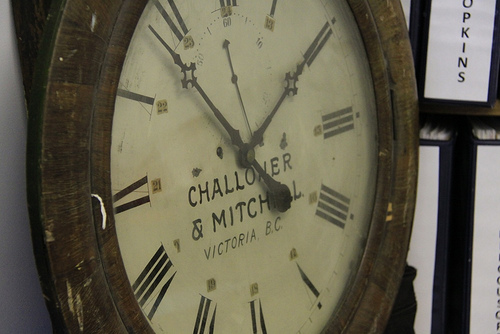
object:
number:
[130, 242, 179, 324]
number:
[315, 105, 363, 140]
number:
[299, 18, 339, 71]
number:
[190, 293, 220, 333]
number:
[293, 258, 323, 297]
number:
[110, 174, 155, 214]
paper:
[420, 0, 495, 103]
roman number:
[245, 297, 270, 333]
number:
[113, 86, 159, 119]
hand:
[248, 36, 318, 149]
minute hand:
[142, 21, 293, 214]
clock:
[10, 0, 422, 333]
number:
[312, 183, 353, 229]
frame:
[5, 0, 422, 333]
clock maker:
[185, 150, 307, 242]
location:
[202, 213, 287, 261]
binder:
[410, 0, 500, 111]